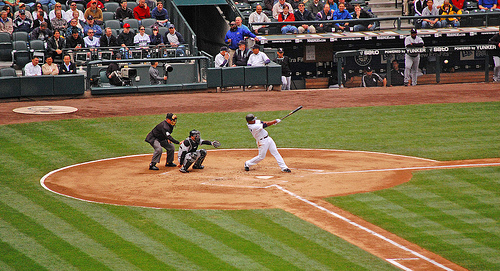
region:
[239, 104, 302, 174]
baseball batter swinging bat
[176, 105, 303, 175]
baseball catcher behind batter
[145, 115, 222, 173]
baseball umpire behind catcher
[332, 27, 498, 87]
player leaning on railing of dugout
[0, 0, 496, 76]
people in stadium bleachers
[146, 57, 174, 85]
man holding large round camera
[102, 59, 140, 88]
person holding large square camera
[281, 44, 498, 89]
players seated in dugout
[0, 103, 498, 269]
green grass has dark and light stripes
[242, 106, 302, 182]
home plate next to batter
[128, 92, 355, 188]
Baseball players on the field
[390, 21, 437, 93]
Person by the fence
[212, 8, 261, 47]
People are wearing blue shirts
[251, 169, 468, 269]
White paint on the ground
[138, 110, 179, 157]
Wearing a black shirt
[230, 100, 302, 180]
Team colors are white and black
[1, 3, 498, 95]
People in the stands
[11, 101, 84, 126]
A plate in the back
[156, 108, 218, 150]
Wearing helmets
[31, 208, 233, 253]
Grass is short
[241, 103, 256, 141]
There is a dark helmet that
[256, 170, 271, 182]
There is a white base at home plate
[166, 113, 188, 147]
There is an umpire helmet here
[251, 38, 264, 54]
There is a hat that visible in the stands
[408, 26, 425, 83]
The manager is standing at the dugout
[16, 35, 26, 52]
There is an empty seat in the stands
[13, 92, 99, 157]
There is a mat on the dirt on the field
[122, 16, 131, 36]
There is a red hat that this man is wearing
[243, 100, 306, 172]
batter swinging a bat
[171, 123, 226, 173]
catcher ready to catch the ball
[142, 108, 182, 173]
umpire standing behind the pitcher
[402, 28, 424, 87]
player standing in the dugout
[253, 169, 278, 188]
home plate on the ground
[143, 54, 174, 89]
camera man standing on the side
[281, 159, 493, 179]
white base line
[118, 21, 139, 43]
man wearing a red hat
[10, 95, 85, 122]
batter's warm up deck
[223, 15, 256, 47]
two men wearing blue jackets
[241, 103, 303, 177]
The man is swinging a bat.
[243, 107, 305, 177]
The man is wearing black shoes.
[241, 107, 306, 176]
The man is wearing a white shirt.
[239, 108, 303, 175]
The man is wearing a black belt.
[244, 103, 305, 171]
The man is wearing white pants.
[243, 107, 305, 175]
The man is wearing a black hat.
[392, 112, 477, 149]
The grass in the background is green.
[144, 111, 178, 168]
The umpire is wearing gray pants.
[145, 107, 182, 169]
The umpire is wearing a black jacket.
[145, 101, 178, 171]
The umpire is wearing black shoes.